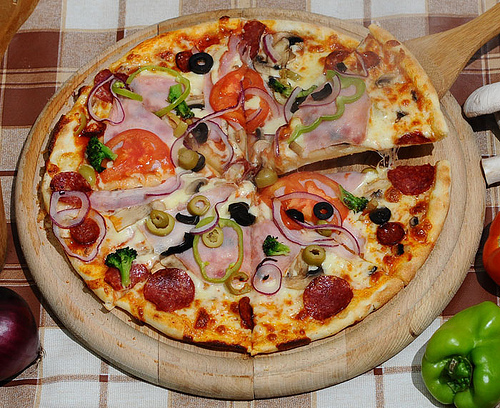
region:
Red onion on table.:
[0, 272, 48, 393]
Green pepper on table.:
[418, 301, 493, 406]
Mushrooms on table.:
[462, 76, 497, 188]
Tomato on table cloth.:
[481, 204, 498, 279]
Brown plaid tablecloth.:
[4, 3, 149, 122]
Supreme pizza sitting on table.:
[32, 11, 452, 357]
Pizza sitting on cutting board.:
[5, 7, 490, 406]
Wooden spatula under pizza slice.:
[397, 4, 494, 109]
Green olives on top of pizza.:
[147, 192, 226, 237]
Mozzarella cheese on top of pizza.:
[87, 64, 417, 304]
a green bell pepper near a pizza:
[403, 289, 490, 397]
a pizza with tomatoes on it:
[69, 33, 377, 262]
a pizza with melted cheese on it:
[52, 60, 444, 360]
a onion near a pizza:
[0, 287, 57, 389]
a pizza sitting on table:
[38, 0, 493, 385]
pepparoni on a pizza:
[140, 240, 242, 322]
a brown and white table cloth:
[23, 11, 106, 111]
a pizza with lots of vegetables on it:
[52, 3, 439, 333]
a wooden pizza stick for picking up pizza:
[388, 0, 497, 96]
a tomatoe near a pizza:
[469, 213, 497, 287]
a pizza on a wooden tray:
[41, 14, 453, 349]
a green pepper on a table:
[423, 295, 497, 405]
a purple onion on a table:
[1, 283, 43, 380]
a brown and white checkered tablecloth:
[4, 0, 498, 407]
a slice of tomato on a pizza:
[104, 132, 174, 187]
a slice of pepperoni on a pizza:
[143, 268, 194, 310]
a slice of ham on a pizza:
[91, 98, 181, 207]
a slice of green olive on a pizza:
[187, 196, 210, 214]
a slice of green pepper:
[286, 64, 363, 152]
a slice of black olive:
[312, 198, 332, 221]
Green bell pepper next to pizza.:
[416, 302, 499, 406]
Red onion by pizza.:
[0, 280, 48, 390]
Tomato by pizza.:
[479, 203, 499, 295]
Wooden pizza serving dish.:
[13, 5, 488, 402]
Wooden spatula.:
[396, 0, 499, 113]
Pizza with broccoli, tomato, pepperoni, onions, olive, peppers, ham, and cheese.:
[41, 11, 456, 357]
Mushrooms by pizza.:
[462, 77, 498, 188]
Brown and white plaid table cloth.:
[1, 0, 498, 407]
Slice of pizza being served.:
[248, 0, 498, 186]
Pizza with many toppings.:
[38, 13, 451, 362]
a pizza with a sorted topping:
[32, 39, 468, 367]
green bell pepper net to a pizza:
[401, 293, 496, 406]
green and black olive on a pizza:
[178, 146, 208, 176]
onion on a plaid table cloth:
[6, 277, 46, 384]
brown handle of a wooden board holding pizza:
[411, 7, 492, 101]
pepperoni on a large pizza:
[136, 264, 194, 311]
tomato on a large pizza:
[116, 132, 173, 190]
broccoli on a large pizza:
[101, 236, 145, 288]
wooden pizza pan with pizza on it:
[214, 345, 396, 395]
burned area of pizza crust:
[37, 112, 56, 237]